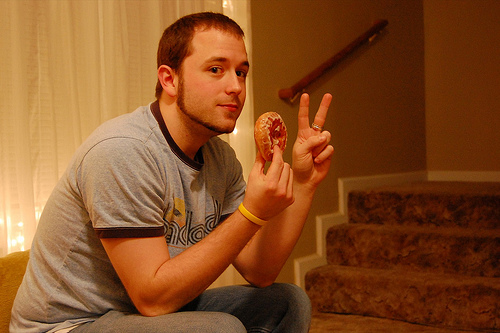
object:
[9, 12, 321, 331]
man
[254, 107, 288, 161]
donut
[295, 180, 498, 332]
stairs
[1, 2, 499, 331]
background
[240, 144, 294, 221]
hand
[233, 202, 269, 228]
wristband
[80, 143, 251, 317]
arm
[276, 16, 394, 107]
railing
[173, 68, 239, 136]
facial hair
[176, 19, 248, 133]
man's face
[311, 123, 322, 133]
ring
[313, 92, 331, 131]
finger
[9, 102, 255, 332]
t-shirt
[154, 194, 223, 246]
design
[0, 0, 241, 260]
curtains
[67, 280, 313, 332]
denim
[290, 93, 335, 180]
hand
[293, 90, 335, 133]
peace sign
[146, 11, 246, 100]
hair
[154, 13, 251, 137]
head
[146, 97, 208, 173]
dark blue edges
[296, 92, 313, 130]
finger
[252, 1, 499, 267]
wall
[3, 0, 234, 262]
window